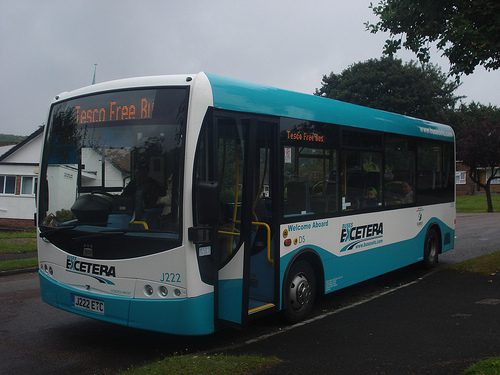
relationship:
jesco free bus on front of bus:
[64, 87, 158, 127] [33, 69, 459, 341]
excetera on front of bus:
[62, 255, 118, 281] [33, 69, 459, 341]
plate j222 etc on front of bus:
[70, 291, 108, 319] [33, 69, 459, 341]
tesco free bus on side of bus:
[285, 127, 326, 146] [33, 69, 459, 341]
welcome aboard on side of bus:
[287, 221, 330, 233] [33, 69, 459, 341]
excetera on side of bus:
[337, 217, 385, 253] [33, 69, 459, 341]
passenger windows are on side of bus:
[279, 113, 458, 224] [33, 69, 459, 341]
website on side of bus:
[353, 237, 384, 250] [33, 69, 459, 341]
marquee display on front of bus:
[64, 87, 158, 127] [33, 69, 459, 341]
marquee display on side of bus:
[64, 87, 158, 127] [33, 69, 459, 341]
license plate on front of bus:
[70, 291, 108, 319] [33, 69, 459, 341]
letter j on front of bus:
[158, 269, 166, 284] [33, 69, 459, 341]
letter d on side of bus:
[296, 233, 303, 246] [33, 69, 459, 341]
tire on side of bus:
[280, 247, 328, 325] [33, 69, 459, 341]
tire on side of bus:
[422, 223, 441, 274] [33, 69, 459, 341]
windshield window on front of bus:
[34, 83, 195, 263] [33, 69, 459, 341]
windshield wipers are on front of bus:
[38, 224, 129, 247] [33, 69, 459, 341]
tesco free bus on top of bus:
[64, 87, 158, 127] [33, 69, 459, 341]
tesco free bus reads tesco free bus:
[64, 87, 158, 127] [64, 87, 158, 127]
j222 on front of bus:
[156, 271, 183, 286] [33, 69, 459, 341]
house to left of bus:
[1, 110, 47, 232] [33, 69, 459, 341]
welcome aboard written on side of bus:
[287, 221, 330, 233] [33, 69, 459, 341]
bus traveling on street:
[33, 69, 459, 341] [1, 211, 499, 373]